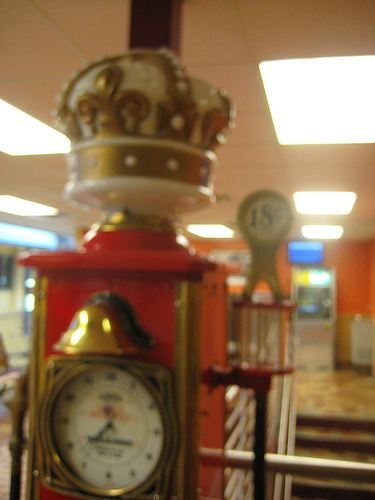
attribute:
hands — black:
[79, 417, 113, 458]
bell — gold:
[50, 289, 154, 365]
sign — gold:
[225, 181, 294, 310]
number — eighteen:
[236, 185, 290, 234]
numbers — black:
[46, 355, 184, 496]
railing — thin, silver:
[191, 413, 372, 490]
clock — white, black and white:
[43, 362, 166, 493]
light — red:
[252, 39, 373, 154]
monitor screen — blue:
[286, 238, 325, 264]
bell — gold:
[46, 289, 166, 359]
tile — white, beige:
[3, 5, 126, 62]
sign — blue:
[285, 236, 325, 267]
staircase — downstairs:
[298, 413, 368, 497]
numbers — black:
[61, 368, 161, 478]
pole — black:
[240, 386, 270, 498]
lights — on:
[251, 28, 370, 171]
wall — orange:
[288, 245, 373, 282]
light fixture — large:
[259, 53, 373, 144]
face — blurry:
[49, 367, 162, 491]